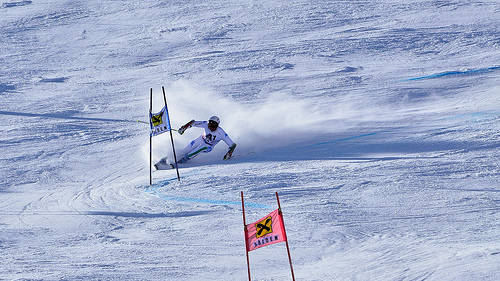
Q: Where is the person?
A: Snow.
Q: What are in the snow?
A: Tracks.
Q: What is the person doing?
A: Man snowboarding.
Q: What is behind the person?
A: Snow in air.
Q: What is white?
A: Snow.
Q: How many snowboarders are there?
A: One.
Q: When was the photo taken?
A: Daytime.